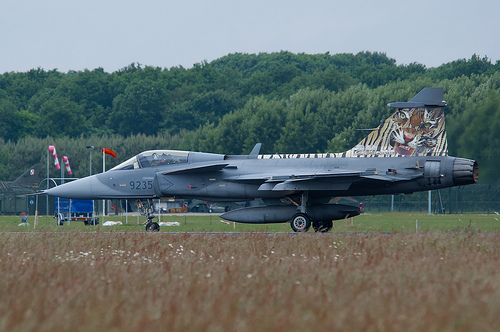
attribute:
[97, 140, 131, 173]
flag — red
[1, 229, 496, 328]
grass — tall, brown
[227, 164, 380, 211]
wing — gray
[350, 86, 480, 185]
tail — large, tall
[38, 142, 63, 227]
flag — tall, red, white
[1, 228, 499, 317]
grass area — large, wide, brown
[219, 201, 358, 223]
fuel tank — external, painted gray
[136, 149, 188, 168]
canopy — glass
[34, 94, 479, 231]
jet — gray, fighter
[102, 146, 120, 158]
windsock — red 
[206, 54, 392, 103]
tree — green 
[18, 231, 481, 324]
grass — brown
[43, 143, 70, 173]
wind socks — red, white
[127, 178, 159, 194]
numbers — black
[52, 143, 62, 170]
wind sock — red, white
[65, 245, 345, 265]
flowers — white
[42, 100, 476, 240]
plane — large, metal, grey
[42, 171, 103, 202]
nose — pointed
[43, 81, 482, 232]
jet — fighter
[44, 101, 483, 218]
jet — fighter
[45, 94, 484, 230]
fighter jet — large, gray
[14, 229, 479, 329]
bush — brown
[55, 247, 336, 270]
flowers — white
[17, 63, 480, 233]
jet — fighter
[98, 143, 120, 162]
flag — red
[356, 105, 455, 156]
print — animal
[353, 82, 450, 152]
tail — plane's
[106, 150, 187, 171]
cockpit — gray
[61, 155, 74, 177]
banner — pink, white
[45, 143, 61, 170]
banner — pink, white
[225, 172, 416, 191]
wing — gray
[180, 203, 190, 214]
barrel — orange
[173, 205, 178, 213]
barrel — orange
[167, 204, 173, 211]
barrel — orange